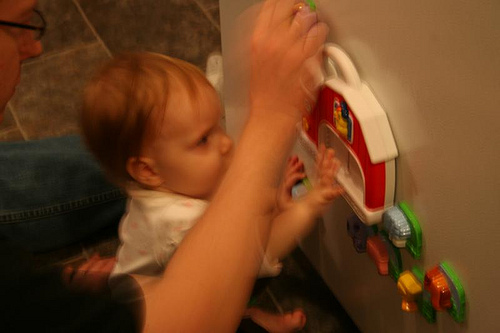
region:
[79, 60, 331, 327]
the baby is playing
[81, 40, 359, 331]
the baby playing with toys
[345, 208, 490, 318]
the toys on the surface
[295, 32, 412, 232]
the large white toy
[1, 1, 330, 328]
the person with glasses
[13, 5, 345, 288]
the person with baby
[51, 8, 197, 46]
the floor is tiled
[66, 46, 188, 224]
hair on the head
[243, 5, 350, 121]
hand on the surface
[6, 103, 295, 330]
arm of the person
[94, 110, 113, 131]
brown hair on head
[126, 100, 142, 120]
brown hair on head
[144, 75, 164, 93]
brown hair on head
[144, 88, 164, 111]
brown hair on head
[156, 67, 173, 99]
brown hair on head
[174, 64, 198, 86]
brown hair on head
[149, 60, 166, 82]
brown hair on head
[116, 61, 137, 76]
brown hair on head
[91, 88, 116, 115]
brown hair on head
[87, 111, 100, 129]
brown hair on head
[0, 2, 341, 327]
adult and child playing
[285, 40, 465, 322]
toy magnets on surface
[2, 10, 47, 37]
glasses on man's face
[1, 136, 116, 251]
denim jeans on legs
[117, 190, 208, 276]
white shirt with pattern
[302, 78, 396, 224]
red and white toy barn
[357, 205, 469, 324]
colored magnets on green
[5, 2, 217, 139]
tile surface on floor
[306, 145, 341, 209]
hand on front of toy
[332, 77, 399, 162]
white roof of barn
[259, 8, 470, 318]
the magnets on the refrigerator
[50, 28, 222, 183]
the baby`s hair is reddish brown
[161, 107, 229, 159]
the eye is open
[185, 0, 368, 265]
the hands are blurry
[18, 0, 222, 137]
the floor is tiled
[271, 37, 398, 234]
the magnet is a farm house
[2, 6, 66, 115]
the man is wearing glasses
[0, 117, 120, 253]
the man is wearing jeans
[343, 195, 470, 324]
the magnets are animals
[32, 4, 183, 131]
the tiles are grayish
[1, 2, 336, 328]
man is wearing eye glasses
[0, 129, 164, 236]
man is wearing blue jeans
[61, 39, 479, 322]
little boy is playing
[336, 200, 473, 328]
magnets on the fridge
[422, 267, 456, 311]
the magnet is orange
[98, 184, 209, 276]
baby's shirt is white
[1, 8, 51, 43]
eye glasses are black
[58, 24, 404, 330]
baby holding barn toy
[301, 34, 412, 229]
barn toy is red and white